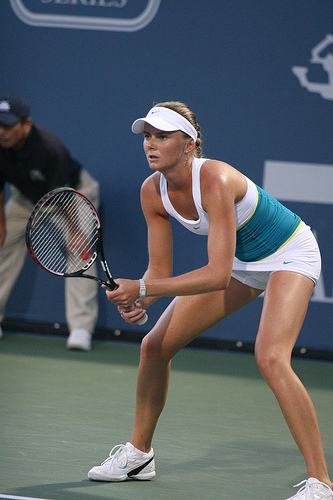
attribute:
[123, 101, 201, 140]
hat — white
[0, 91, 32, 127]
hat — black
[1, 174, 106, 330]
pants — tan